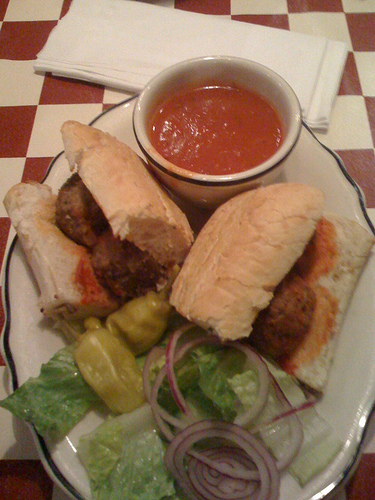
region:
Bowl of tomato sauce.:
[137, 55, 303, 207]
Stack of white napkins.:
[35, 0, 346, 130]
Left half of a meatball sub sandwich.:
[4, 120, 190, 333]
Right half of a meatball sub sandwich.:
[168, 180, 370, 378]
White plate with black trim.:
[0, 90, 369, 488]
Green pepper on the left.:
[68, 315, 139, 406]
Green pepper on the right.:
[105, 263, 180, 347]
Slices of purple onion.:
[140, 318, 297, 494]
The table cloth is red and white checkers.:
[1, 1, 373, 171]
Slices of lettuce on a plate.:
[4, 332, 340, 497]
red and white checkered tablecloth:
[1, 1, 373, 499]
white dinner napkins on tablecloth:
[31, 2, 350, 135]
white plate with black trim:
[0, 81, 374, 498]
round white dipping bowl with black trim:
[129, 51, 303, 189]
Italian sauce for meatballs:
[150, 78, 281, 174]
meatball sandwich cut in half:
[0, 119, 374, 393]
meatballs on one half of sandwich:
[55, 179, 161, 293]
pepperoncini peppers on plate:
[73, 263, 181, 413]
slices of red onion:
[141, 318, 319, 498]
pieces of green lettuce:
[0, 314, 347, 498]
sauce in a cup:
[181, 77, 282, 144]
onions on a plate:
[165, 423, 259, 495]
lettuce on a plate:
[83, 417, 152, 477]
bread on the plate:
[203, 166, 359, 329]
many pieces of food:
[17, 184, 325, 473]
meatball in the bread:
[247, 263, 328, 353]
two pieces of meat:
[49, 174, 159, 317]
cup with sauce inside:
[222, 44, 297, 96]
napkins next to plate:
[21, 11, 128, 94]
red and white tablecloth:
[0, 70, 80, 143]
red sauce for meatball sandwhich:
[145, 65, 311, 193]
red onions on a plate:
[164, 414, 267, 499]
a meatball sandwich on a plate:
[60, 177, 152, 324]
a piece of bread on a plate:
[211, 189, 292, 324]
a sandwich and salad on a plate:
[32, 165, 341, 477]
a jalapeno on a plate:
[83, 323, 145, 416]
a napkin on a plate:
[58, 18, 289, 93]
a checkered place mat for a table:
[8, 14, 57, 132]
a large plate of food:
[45, 68, 366, 488]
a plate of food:
[19, 71, 345, 477]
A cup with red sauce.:
[129, 56, 304, 207]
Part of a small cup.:
[247, 63, 275, 87]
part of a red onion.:
[178, 431, 196, 446]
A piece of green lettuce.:
[0, 350, 99, 442]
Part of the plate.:
[16, 327, 31, 344]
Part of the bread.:
[204, 273, 237, 303]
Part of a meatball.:
[252, 278, 314, 359]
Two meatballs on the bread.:
[53, 174, 159, 296]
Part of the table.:
[18, 104, 55, 155]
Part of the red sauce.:
[322, 244, 334, 267]